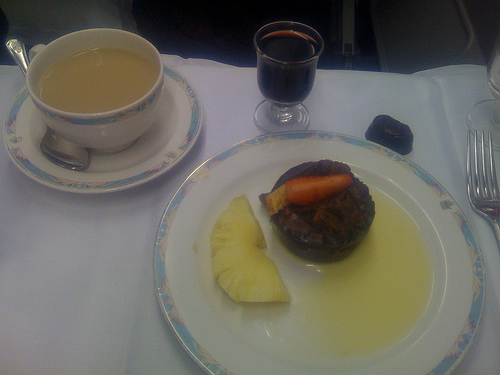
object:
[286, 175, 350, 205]
carrot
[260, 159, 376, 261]
meat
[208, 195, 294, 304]
pineapple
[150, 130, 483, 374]
plate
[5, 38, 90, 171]
spoon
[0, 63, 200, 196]
saucer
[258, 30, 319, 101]
liquid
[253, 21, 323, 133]
glass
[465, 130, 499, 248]
fork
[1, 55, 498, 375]
tablecloth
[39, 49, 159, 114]
gravy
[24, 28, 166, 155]
cup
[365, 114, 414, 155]
chocolate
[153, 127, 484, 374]
design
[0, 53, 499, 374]
table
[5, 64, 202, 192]
trim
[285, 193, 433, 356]
sauce